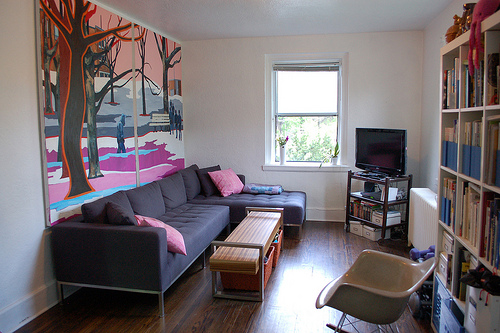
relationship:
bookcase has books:
[430, 11, 499, 332] [432, 31, 500, 331]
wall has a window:
[182, 35, 422, 223] [274, 68, 339, 163]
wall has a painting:
[0, 0, 185, 332] [34, 1, 188, 228]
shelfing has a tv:
[344, 170, 412, 244] [356, 127, 406, 174]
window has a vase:
[274, 68, 339, 163] [280, 145, 287, 163]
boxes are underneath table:
[221, 245, 273, 292] [211, 206, 285, 304]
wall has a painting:
[182, 35, 422, 223] [34, 1, 188, 228]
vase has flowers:
[280, 145, 287, 163] [278, 137, 289, 146]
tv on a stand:
[356, 127, 406, 174] [344, 170, 412, 241]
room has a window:
[2, 2, 498, 332] [274, 68, 339, 163]